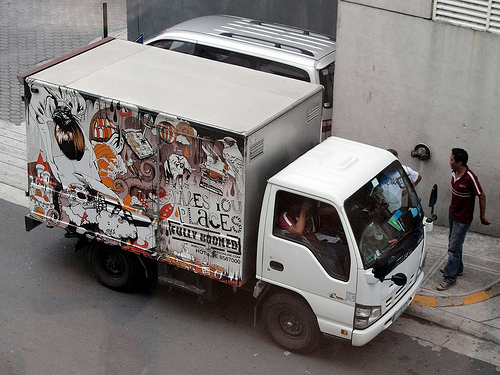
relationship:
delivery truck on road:
[17, 36, 429, 351] [7, 273, 295, 373]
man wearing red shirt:
[435, 148, 494, 291] [445, 168, 485, 223]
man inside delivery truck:
[274, 193, 343, 245] [17, 36, 429, 351]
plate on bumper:
[387, 295, 410, 324] [346, 265, 429, 348]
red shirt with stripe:
[449, 165, 484, 224] [464, 169, 483, 194]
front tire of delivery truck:
[259, 289, 321, 352] [17, 36, 429, 351]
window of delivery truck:
[342, 160, 424, 269] [17, 36, 429, 351]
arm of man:
[472, 171, 484, 234] [420, 140, 491, 321]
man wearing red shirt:
[435, 148, 494, 291] [449, 165, 484, 224]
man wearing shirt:
[435, 148, 494, 291] [375, 167, 418, 209]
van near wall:
[139, 14, 337, 144] [337, 1, 496, 247]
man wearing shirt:
[279, 195, 352, 270] [279, 208, 317, 237]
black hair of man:
[452, 147, 467, 165] [435, 148, 494, 291]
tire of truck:
[65, 231, 159, 278] [81, 81, 461, 368]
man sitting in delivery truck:
[435, 148, 494, 291] [17, 36, 429, 351]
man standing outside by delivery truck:
[435, 148, 494, 291] [17, 36, 429, 351]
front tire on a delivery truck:
[259, 289, 321, 352] [21, 36, 431, 361]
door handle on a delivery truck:
[267, 256, 285, 274] [17, 36, 429, 351]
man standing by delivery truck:
[435, 148, 494, 291] [17, 36, 429, 351]